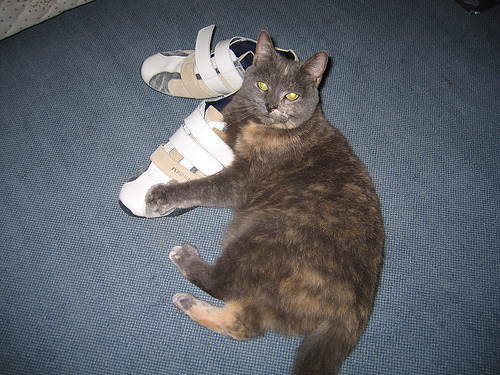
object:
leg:
[172, 292, 270, 341]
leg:
[144, 161, 242, 215]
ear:
[252, 30, 276, 65]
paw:
[145, 182, 179, 216]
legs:
[169, 242, 250, 298]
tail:
[294, 324, 370, 373]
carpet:
[0, 0, 500, 373]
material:
[5, 0, 74, 34]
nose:
[265, 97, 280, 111]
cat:
[145, 30, 387, 375]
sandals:
[140, 23, 295, 99]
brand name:
[172, 166, 191, 181]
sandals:
[118, 81, 326, 219]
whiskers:
[224, 104, 260, 127]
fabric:
[1, 0, 86, 39]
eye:
[285, 91, 299, 101]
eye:
[256, 81, 269, 91]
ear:
[301, 51, 329, 82]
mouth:
[267, 116, 294, 128]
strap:
[215, 35, 243, 94]